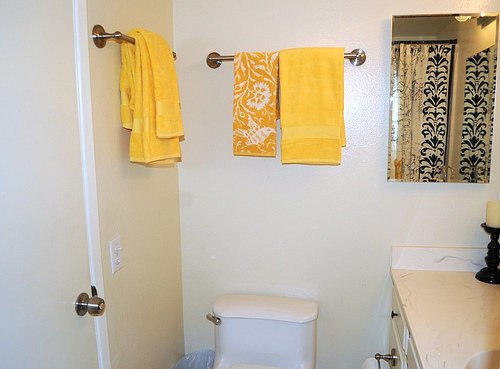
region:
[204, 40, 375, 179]
two towels on the rack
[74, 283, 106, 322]
silver doorknob on the door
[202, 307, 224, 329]
handle to flush the toliet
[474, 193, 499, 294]
candle in a holder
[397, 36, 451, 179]
shower curtain in the mirror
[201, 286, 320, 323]
cover of the toliet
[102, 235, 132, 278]
light switch on the wall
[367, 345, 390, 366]
handle on the cupboard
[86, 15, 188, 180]
yellow towels on the rack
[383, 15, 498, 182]
mirror on the wall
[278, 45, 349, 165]
A hanging yellow towel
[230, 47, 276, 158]
A hanging yellow and white towel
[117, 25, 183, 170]
A hanging yellow towel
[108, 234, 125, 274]
A white plate on the wall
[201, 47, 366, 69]
a metal bar on the wall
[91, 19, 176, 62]
a metal bar on the wall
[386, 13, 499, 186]
A mirror on the wall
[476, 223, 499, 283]
a black candle holder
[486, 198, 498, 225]
a white candle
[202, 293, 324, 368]
A white toilet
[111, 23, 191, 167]
a yellow hand towel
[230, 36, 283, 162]
an orange hand towel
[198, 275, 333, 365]
tank of a toilet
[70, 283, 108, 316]
knob of a door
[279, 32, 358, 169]
yellow hand towel hanged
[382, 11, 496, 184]
a mirror on the wall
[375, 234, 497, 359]
a sink counter top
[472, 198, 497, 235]
candles on a sink top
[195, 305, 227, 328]
flush lever of a tank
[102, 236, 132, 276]
light switches on wall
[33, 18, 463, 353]
Picture is taken in bathroom.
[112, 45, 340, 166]
Towels are yellow color.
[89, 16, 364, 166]
Towel are hanging in the hanger.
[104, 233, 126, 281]
Switch is white color.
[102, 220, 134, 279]
Switch is hanging in the wall.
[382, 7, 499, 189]
Mirror is hanging in the wall.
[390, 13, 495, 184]
Reflection is seen in mirror.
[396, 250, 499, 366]
Counter is white color.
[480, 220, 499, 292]
Stand is in counter.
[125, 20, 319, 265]
Wall is white color.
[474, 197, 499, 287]
a candle on the bathroom counter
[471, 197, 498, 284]
the candle sits on a carved candlestick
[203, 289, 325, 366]
the toilet is white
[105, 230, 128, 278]
the bathroom light is switched on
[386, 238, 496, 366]
the bathroom countertop is white marble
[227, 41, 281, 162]
this bath towel has a flower pattern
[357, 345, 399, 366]
the bath tissue roll is to the right of the toilet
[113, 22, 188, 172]
these bath towels are gold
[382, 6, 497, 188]
the medicine chest reflects the shower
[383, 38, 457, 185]
the shower curtain has a kind of fleur-de-lis pattern